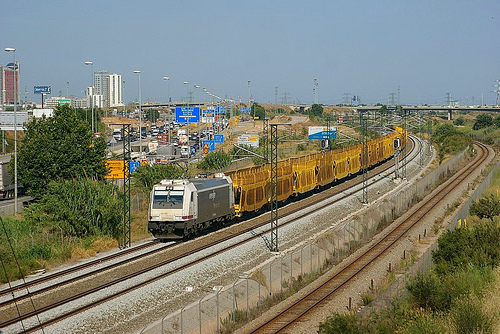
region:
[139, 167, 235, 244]
section of a train on the tracks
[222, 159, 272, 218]
section of a train on the tracks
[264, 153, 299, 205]
section of a train on the tracks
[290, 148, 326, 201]
section of a train on the tracks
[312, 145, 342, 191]
section of a train on the tracks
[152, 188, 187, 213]
windshield on a train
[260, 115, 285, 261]
metal tower next to train tracks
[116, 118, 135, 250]
metal tower next to train tracks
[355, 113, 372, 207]
metal tower next to train tracks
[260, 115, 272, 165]
metal tower next to train tracks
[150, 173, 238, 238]
Silver train engine on track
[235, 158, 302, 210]
Yellow train car behind engine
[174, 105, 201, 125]
Blue sign over highway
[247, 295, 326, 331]
Rusted train track below train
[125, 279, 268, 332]
Silver metal fence beside tracks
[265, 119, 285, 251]
Tall steel frame near tracks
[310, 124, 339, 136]
Blue and white billboard near train tracks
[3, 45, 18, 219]
Tall street light on pole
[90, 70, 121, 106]
Tall white building with many windows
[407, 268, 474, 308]
Leafy green bush beside train tracks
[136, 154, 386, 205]
The train is on the track.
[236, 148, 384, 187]
The train cars are yellow.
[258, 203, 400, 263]
A fence around the tracks.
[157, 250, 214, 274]
Rocks in between the tracks.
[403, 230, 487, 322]
Trees on the side of the track.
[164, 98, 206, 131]
Blue highway signs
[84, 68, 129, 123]
The white building in the background.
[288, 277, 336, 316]
The tracks on the side of the fence.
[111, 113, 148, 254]
Iron poles on the side of the track.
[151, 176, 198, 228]
The train is white in the front.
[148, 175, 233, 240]
train engine pulling lots of cars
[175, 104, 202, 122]
blue traffic sign over road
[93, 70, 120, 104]
tall white building near overpass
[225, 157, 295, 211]
yellow train car being towed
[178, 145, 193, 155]
recreational vehicle driving on road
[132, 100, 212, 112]
overpass running over road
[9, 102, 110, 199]
big green tree growing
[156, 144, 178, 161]
diesel truck driving on road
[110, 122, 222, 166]
lots of traffic driving on road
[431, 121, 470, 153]
some bushes growing on side of tracks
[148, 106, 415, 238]
train traveling down the tracks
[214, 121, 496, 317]
unused train tracks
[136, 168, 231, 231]
white and gray front car of train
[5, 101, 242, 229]
roads running beside train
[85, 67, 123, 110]
skyscraper in the skyline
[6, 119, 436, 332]
gravel surrounding train tracks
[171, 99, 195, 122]
blue sign with white lettering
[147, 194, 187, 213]
front window of train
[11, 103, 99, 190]
tree growing beside road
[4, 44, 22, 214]
white street light next to road